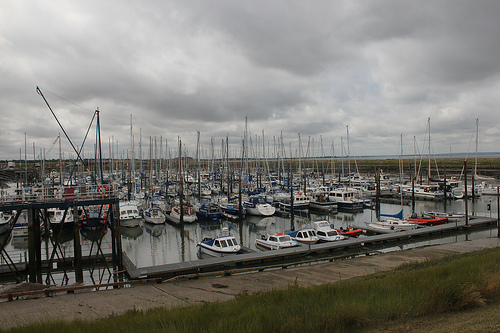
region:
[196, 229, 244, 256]
Small boat docked at the harbor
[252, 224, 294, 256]
Small boat docked at the harbor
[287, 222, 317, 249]
Small boat docked at the harbor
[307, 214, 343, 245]
Small boat docked at the harbor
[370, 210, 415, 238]
Small boat docked at the harbor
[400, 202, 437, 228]
Small boat docked at the harbor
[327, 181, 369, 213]
Small boat docked at the harbor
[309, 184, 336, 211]
Small boat docked at the harbor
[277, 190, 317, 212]
Small boat docked at the harbor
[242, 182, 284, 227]
Small boat docked at the harbor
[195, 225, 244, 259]
The boat is parked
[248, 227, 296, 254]
The boat is parked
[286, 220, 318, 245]
The boat is parked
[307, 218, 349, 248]
The boat is parked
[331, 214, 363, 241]
The boat is parked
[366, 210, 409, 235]
The boat is parked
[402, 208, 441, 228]
The boat is parked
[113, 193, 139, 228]
The boat is parked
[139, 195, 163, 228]
The boat is parked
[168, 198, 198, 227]
The boat is parked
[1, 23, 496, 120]
clouds in the sky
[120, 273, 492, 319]
grass in front of the boats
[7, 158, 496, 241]
boats in the water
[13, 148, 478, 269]
boats in the harbor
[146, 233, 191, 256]
small waves in the water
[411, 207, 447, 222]
a red boat in the water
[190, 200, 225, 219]
a blue boat in the water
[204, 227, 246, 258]
a white boat in the water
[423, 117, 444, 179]
a pole on the boat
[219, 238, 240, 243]
windows on the boat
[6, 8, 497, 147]
The sky is cloudy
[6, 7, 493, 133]
The sky is overcast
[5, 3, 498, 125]
The sky is grey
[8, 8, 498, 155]
The sky is threatening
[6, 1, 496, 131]
The sky is gloomy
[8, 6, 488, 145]
The sky is heavy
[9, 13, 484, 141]
The sky is sunless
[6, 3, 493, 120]
The sky is hazy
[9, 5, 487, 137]
The sky is precarious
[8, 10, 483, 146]
The sky is dismal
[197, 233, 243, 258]
white and black boat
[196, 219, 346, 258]
four boats that are in the water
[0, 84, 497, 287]
harbor full of boats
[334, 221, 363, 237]
red boat in the harbor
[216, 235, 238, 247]
windshield of the boat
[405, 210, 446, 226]
right side of the red boat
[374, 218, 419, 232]
harbor holding the white boat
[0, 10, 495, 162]
gray cloudy clouds above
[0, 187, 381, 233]
second row of boats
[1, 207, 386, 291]
water the boats are sitting in